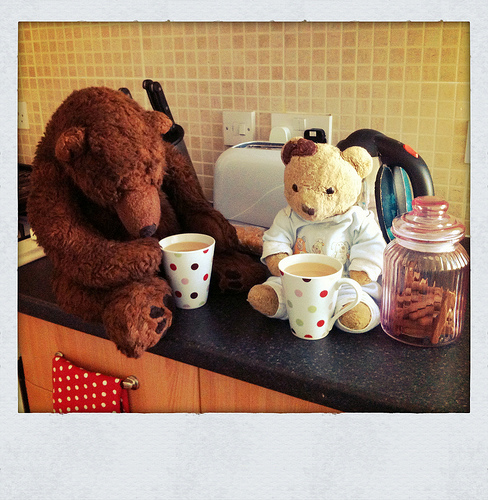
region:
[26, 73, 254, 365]
brown teddy bear sitting on counter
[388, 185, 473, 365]
cookie jar with cookies inside sitting on the counter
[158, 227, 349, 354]
two cups of coffee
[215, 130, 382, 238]
a toaster behind the bear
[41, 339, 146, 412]
a dishtowel hanging on a towel rack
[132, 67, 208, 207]
two knives in a rack behind the brown bear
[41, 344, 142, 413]
a red towel with white polka dots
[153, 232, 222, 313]
a white coffee cup with polka dots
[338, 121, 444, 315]
an iron sitting beside the wall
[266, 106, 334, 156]
electrical box on the wall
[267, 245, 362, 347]
White cup with polka dots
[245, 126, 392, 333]
Light brown teddy bear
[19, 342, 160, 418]
Red towel with white dots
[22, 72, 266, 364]
Very large dark brown bear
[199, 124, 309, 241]
White toaster in background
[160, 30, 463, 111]
small tiles on a wall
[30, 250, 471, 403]
A dark counter top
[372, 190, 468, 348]
A glass container with snacks in it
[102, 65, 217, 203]
Black handled knives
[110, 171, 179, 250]
A very long bear nose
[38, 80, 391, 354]
two stuffed animals on the counter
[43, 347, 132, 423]
red with white polka dot towel hanging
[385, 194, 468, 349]
a clear jar with some sort of snack in it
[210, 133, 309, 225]
a nice white clean toaster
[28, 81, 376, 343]
two stuffed animals drinking coffee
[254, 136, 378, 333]
a vanilla color teddy bear with one brown ear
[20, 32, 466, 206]
tiny yellowish squares that make up the wall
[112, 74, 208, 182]
a set of knives with black handles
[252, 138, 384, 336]
a teddy bear wearing a onesie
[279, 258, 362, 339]
a polka dotted coffee cup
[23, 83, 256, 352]
a stuffed animal sitting behind a mug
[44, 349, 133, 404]
a red and white towel hanging on a towel rack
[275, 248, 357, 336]
a polka dotted mug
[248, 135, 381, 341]
a stuffed animal sitting behind a mug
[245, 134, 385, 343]
a stuffed animal wearing a white outfit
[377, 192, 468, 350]
a pink clear cookie jar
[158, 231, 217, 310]
a mug with a polka dot design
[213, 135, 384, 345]
a white toast positioned behind a stuffed animal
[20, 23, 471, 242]
yellow wall tiles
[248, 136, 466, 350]
a stuffed animal sitting next to a cookie jar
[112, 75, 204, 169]
Knives with black handles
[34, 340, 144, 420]
red towel with white dots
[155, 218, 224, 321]
white cup with polka dots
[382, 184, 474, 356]
glass container with food in it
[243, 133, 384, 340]
light colored teddy bear with clothes on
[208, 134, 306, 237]
white toaster sitting on counter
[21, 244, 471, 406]
Dark colored counter top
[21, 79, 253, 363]
Large dark brown colored teddy bear with long nose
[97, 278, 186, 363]
bears dark colored large foot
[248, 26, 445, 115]
small light colored tiles